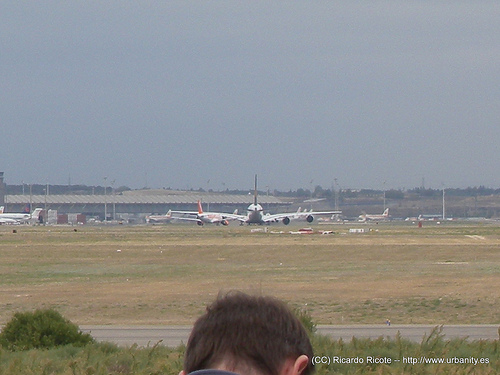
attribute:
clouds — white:
[397, 7, 499, 40]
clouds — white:
[255, 53, 371, 108]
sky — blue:
[24, 22, 489, 162]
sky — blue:
[226, 49, 362, 129]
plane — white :
[173, 174, 341, 226]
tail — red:
[195, 200, 206, 217]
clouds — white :
[27, 16, 498, 135]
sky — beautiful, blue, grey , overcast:
[2, 3, 496, 189]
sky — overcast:
[65, 26, 440, 167]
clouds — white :
[161, 64, 467, 167]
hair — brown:
[182, 287, 322, 363]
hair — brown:
[184, 293, 341, 373]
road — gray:
[74, 322, 496, 350]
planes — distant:
[197, 205, 339, 231]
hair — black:
[180, 286, 326, 373]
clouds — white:
[362, 94, 480, 182]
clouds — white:
[234, 52, 311, 157]